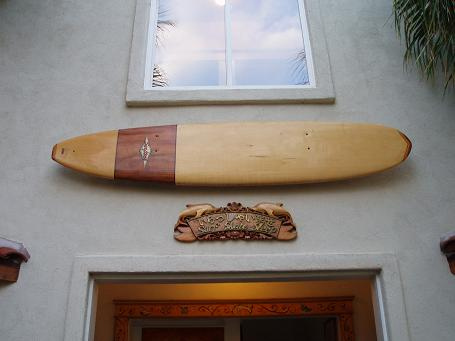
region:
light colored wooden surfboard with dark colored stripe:
[52, 120, 412, 184]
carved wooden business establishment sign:
[174, 201, 298, 241]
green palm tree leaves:
[379, 2, 453, 100]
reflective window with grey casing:
[125, 0, 334, 101]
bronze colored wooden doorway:
[95, 278, 378, 339]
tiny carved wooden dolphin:
[246, 200, 295, 227]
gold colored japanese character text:
[194, 211, 275, 227]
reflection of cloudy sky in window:
[143, 0, 317, 89]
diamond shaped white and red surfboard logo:
[139, 136, 151, 167]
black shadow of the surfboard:
[54, 120, 415, 196]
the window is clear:
[125, 13, 302, 189]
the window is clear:
[117, 1, 261, 72]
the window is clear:
[129, 8, 418, 316]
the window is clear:
[125, 4, 346, 119]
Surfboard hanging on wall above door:
[44, 114, 434, 187]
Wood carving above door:
[160, 186, 315, 252]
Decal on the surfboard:
[112, 110, 177, 181]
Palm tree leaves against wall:
[387, 1, 453, 80]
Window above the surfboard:
[137, 2, 338, 103]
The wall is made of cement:
[0, 179, 46, 232]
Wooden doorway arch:
[92, 273, 426, 338]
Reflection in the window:
[144, 5, 318, 107]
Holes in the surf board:
[152, 126, 177, 172]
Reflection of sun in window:
[191, 0, 249, 14]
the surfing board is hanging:
[39, 120, 435, 227]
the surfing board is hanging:
[31, 84, 280, 201]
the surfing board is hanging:
[26, 53, 443, 337]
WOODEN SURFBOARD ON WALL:
[51, 118, 417, 175]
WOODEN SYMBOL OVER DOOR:
[141, 185, 309, 264]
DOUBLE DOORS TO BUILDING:
[65, 274, 408, 331]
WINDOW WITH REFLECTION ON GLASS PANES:
[154, 0, 317, 83]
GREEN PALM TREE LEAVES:
[385, 7, 454, 74]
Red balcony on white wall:
[4, 235, 37, 292]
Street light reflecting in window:
[203, 0, 240, 20]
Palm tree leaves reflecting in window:
[132, 53, 181, 101]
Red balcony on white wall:
[433, 209, 453, 280]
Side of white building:
[0, 8, 447, 321]